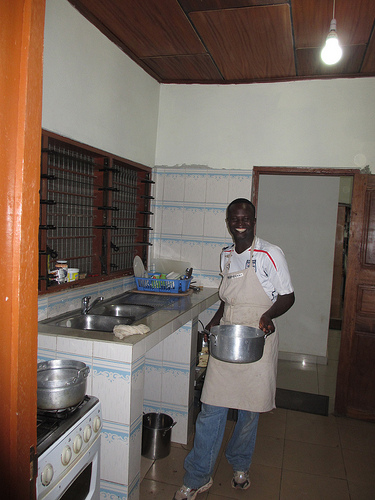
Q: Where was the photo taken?
A: It was taken at the kitchen.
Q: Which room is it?
A: It is a kitchen.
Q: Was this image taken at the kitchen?
A: Yes, it was taken in the kitchen.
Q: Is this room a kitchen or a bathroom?
A: It is a kitchen.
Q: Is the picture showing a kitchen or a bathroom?
A: It is showing a kitchen.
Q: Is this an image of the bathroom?
A: No, the picture is showing the kitchen.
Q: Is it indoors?
A: Yes, it is indoors.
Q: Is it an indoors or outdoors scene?
A: It is indoors.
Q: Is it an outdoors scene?
A: No, it is indoors.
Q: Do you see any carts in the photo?
A: No, there are no carts.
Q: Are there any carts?
A: No, there are no carts.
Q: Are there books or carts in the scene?
A: No, there are no carts or books.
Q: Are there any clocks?
A: No, there are no clocks.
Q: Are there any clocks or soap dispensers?
A: No, there are no clocks or soap dispensers.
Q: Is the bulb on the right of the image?
A: Yes, the bulb is on the right of the image.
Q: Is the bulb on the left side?
A: No, the bulb is on the right of the image.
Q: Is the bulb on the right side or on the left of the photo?
A: The bulb is on the right of the image.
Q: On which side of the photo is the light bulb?
A: The light bulb is on the right of the image.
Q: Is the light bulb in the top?
A: Yes, the light bulb is in the top of the image.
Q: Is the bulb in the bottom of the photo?
A: No, the bulb is in the top of the image.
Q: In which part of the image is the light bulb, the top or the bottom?
A: The light bulb is in the top of the image.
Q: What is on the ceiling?
A: The light bulb is on the ceiling.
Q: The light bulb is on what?
A: The light bulb is on the ceiling.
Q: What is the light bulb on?
A: The light bulb is on the ceiling.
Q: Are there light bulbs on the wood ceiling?
A: Yes, there is a light bulb on the ceiling.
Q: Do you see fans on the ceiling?
A: No, there is a light bulb on the ceiling.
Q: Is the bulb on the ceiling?
A: Yes, the bulb is on the ceiling.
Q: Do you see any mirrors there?
A: No, there are no mirrors.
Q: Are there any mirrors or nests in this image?
A: No, there are no mirrors or nests.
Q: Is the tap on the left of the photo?
A: Yes, the tap is on the left of the image.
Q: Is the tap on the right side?
A: No, the tap is on the left of the image.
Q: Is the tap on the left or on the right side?
A: The tap is on the left of the image.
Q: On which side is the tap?
A: The tap is on the left of the image.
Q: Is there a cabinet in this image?
A: No, there are no cabinets.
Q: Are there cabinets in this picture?
A: No, there are no cabinets.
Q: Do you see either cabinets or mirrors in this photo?
A: No, there are no cabinets or mirrors.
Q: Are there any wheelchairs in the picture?
A: No, there are no wheelchairs.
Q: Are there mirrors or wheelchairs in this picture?
A: No, there are no wheelchairs or mirrors.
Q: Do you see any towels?
A: Yes, there is a towel.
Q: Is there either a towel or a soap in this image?
A: Yes, there is a towel.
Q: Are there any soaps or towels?
A: Yes, there is a towel.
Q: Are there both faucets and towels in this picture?
A: Yes, there are both a towel and a faucet.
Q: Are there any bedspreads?
A: No, there are no bedspreads.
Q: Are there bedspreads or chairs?
A: No, there are no bedspreads or chairs.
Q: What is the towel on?
A: The towel is on the counter.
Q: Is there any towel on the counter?
A: Yes, there is a towel on the counter.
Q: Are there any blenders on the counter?
A: No, there is a towel on the counter.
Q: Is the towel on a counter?
A: Yes, the towel is on a counter.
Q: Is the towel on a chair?
A: No, the towel is on a counter.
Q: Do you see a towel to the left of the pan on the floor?
A: Yes, there is a towel to the left of the pan.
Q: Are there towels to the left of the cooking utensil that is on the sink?
A: Yes, there is a towel to the left of the pan.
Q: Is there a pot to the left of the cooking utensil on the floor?
A: No, there is a towel to the left of the pan.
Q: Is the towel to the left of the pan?
A: Yes, the towel is to the left of the pan.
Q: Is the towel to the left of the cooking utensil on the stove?
A: Yes, the towel is to the left of the pan.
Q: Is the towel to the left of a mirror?
A: No, the towel is to the left of the pan.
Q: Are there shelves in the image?
A: No, there are no shelves.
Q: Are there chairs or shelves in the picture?
A: No, there are no shelves or chairs.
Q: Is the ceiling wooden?
A: Yes, the ceiling is wooden.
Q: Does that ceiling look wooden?
A: Yes, the ceiling is wooden.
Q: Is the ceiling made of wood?
A: Yes, the ceiling is made of wood.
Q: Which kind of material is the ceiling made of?
A: The ceiling is made of wood.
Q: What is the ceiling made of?
A: The ceiling is made of wood.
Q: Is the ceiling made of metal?
A: No, the ceiling is made of wood.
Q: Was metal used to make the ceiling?
A: No, the ceiling is made of wood.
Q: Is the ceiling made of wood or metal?
A: The ceiling is made of wood.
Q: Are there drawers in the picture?
A: No, there are no drawers.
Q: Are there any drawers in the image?
A: No, there are no drawers.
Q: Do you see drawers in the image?
A: No, there are no drawers.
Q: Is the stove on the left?
A: Yes, the stove is on the left of the image.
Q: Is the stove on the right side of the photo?
A: No, the stove is on the left of the image.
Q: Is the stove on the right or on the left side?
A: The stove is on the left of the image.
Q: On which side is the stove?
A: The stove is on the left of the image.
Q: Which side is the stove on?
A: The stove is on the left of the image.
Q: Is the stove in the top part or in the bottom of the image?
A: The stove is in the bottom of the image.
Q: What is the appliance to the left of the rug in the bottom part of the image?
A: The appliance is a stove.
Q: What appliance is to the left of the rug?
A: The appliance is a stove.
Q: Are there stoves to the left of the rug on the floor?
A: Yes, there is a stove to the left of the rug.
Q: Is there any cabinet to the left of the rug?
A: No, there is a stove to the left of the rug.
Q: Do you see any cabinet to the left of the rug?
A: No, there is a stove to the left of the rug.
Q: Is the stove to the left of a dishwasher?
A: No, the stove is to the left of the rug.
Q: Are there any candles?
A: No, there are no candles.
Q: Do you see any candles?
A: No, there are no candles.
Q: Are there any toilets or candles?
A: No, there are no candles or toilets.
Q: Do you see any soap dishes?
A: No, there are no soap dishes.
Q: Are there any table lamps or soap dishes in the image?
A: No, there are no soap dishes or table lamps.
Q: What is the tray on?
A: The tray is on the sink.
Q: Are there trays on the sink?
A: Yes, there is a tray on the sink.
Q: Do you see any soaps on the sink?
A: No, there is a tray on the sink.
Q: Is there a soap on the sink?
A: No, there is a tray on the sink.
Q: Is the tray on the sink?
A: Yes, the tray is on the sink.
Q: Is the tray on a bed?
A: No, the tray is on the sink.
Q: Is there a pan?
A: Yes, there is a pan.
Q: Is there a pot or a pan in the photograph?
A: Yes, there is a pan.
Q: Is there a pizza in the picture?
A: No, there are no pizzas.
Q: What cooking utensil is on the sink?
A: The cooking utensil is a pan.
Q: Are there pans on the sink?
A: Yes, there is a pan on the sink.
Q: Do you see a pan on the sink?
A: Yes, there is a pan on the sink.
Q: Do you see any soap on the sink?
A: No, there is a pan on the sink.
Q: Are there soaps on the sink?
A: No, there is a pan on the sink.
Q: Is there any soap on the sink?
A: No, there is a pan on the sink.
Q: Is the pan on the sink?
A: Yes, the pan is on the sink.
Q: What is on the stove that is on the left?
A: The pan is on the stove.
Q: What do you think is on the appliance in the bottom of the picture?
A: The pan is on the stove.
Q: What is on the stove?
A: The pan is on the stove.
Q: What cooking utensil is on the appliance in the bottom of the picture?
A: The cooking utensil is a pan.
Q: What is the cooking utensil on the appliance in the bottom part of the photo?
A: The cooking utensil is a pan.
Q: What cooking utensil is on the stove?
A: The cooking utensil is a pan.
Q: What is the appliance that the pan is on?
A: The appliance is a stove.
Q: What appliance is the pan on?
A: The pan is on the stove.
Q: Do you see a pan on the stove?
A: Yes, there is a pan on the stove.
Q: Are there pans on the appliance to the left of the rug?
A: Yes, there is a pan on the stove.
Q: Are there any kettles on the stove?
A: No, there is a pan on the stove.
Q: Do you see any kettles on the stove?
A: No, there is a pan on the stove.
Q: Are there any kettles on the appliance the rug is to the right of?
A: No, there is a pan on the stove.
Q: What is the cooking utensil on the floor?
A: The cooking utensil is a pan.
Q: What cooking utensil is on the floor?
A: The cooking utensil is a pan.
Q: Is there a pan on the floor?
A: Yes, there is a pan on the floor.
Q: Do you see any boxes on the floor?
A: No, there is a pan on the floor.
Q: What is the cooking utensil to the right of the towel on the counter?
A: The cooking utensil is a pan.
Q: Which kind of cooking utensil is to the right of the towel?
A: The cooking utensil is a pan.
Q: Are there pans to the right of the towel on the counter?
A: Yes, there is a pan to the right of the towel.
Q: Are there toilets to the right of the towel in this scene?
A: No, there is a pan to the right of the towel.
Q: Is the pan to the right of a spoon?
A: No, the pan is to the right of a towel.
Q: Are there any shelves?
A: No, there are no shelves.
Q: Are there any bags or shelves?
A: No, there are no shelves or bags.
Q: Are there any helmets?
A: No, there are no helmets.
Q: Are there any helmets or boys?
A: No, there are no helmets or boys.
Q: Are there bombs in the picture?
A: No, there are no bombs.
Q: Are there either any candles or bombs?
A: No, there are no bombs or candles.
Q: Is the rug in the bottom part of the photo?
A: Yes, the rug is in the bottom of the image.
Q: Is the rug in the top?
A: No, the rug is in the bottom of the image.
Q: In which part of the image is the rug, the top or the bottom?
A: The rug is in the bottom of the image.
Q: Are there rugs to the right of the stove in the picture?
A: Yes, there is a rug to the right of the stove.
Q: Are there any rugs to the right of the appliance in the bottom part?
A: Yes, there is a rug to the right of the stove.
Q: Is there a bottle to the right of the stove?
A: No, there is a rug to the right of the stove.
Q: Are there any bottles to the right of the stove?
A: No, there is a rug to the right of the stove.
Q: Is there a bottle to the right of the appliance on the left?
A: No, there is a rug to the right of the stove.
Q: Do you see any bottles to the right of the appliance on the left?
A: No, there is a rug to the right of the stove.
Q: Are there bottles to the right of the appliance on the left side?
A: No, there is a rug to the right of the stove.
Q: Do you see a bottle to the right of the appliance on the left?
A: No, there is a rug to the right of the stove.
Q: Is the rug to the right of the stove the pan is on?
A: Yes, the rug is to the right of the stove.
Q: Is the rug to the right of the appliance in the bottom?
A: Yes, the rug is to the right of the stove.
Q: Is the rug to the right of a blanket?
A: No, the rug is to the right of the stove.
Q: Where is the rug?
A: The rug is on the floor.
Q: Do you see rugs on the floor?
A: Yes, there is a rug on the floor.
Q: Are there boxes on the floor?
A: No, there is a rug on the floor.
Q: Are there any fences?
A: No, there are no fences.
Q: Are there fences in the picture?
A: No, there are no fences.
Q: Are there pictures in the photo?
A: No, there are no pictures.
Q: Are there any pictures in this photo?
A: No, there are no pictures.